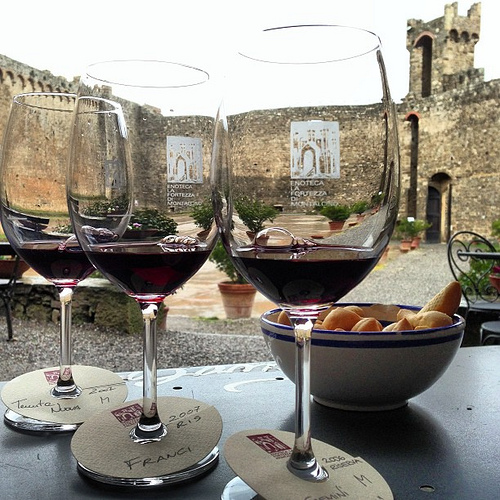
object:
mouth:
[238, 25, 381, 65]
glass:
[211, 23, 401, 498]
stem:
[288, 306, 321, 474]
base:
[223, 430, 393, 500]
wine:
[230, 246, 382, 304]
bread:
[417, 280, 463, 316]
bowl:
[257, 301, 464, 413]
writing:
[122, 455, 140, 471]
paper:
[70, 397, 222, 477]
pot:
[218, 280, 257, 320]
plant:
[232, 191, 279, 237]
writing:
[294, 191, 301, 198]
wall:
[385, 0, 500, 247]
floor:
[335, 243, 467, 305]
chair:
[446, 229, 499, 345]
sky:
[0, 0, 500, 117]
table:
[0, 342, 500, 498]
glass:
[66, 59, 226, 492]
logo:
[289, 121, 340, 178]